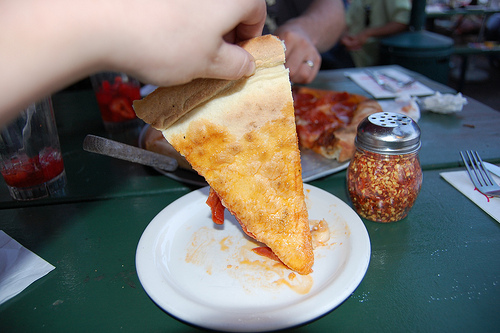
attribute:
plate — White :
[128, 170, 373, 327]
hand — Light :
[106, 0, 281, 92]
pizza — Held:
[131, 31, 316, 274]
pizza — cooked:
[186, 70, 344, 300]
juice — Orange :
[183, 216, 313, 305]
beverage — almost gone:
[3, 155, 62, 186]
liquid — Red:
[7, 146, 47, 191]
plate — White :
[123, 164, 383, 324]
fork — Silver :
[442, 141, 499, 205]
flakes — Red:
[347, 147, 423, 223]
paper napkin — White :
[438, 158, 498, 227]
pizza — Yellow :
[133, 27, 374, 279]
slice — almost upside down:
[128, 22, 330, 284]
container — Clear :
[348, 111, 416, 213]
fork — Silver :
[436, 145, 499, 222]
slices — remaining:
[285, 78, 389, 163]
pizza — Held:
[121, 45, 403, 259]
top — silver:
[351, 109, 422, 154]